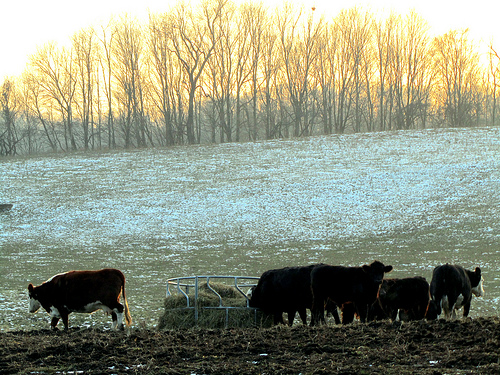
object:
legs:
[100, 304, 118, 328]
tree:
[31, 40, 80, 151]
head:
[26, 283, 40, 315]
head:
[470, 266, 486, 298]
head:
[361, 260, 393, 284]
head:
[245, 284, 263, 309]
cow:
[24, 268, 133, 332]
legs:
[60, 314, 69, 333]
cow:
[308, 259, 393, 328]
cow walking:
[25, 267, 134, 332]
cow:
[430, 262, 487, 322]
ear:
[27, 283, 33, 291]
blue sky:
[0, 0, 500, 125]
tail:
[122, 273, 133, 328]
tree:
[161, 0, 226, 146]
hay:
[156, 281, 260, 329]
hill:
[0, 126, 500, 334]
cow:
[375, 275, 429, 322]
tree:
[0, 76, 31, 157]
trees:
[430, 28, 470, 128]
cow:
[244, 261, 327, 329]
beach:
[0, 316, 500, 375]